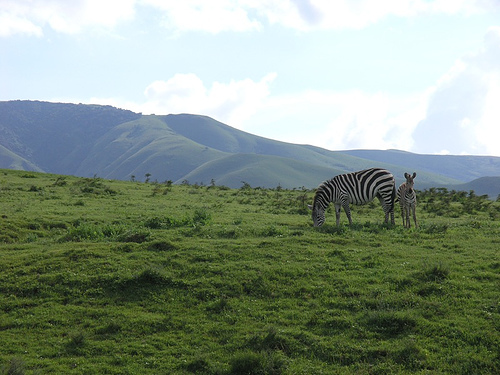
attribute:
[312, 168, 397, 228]
zebra — black, white, bending over, grazing, standing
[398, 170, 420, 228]
zebra — standing, young, looking, baby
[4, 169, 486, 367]
mountain — green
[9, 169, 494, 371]
ground — green, grassy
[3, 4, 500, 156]
sky — blue, overcast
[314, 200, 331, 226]
head — down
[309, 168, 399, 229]
stripes — black, white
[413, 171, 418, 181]
ear — pointy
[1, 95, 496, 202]
mountains — green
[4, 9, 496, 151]
clouds — white, puffy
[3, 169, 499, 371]
grass — pastured, green, nice, heavy, plush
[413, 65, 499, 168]
cloud — large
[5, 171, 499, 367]
bushes — green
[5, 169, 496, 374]
land — grassy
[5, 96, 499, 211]
hills — large